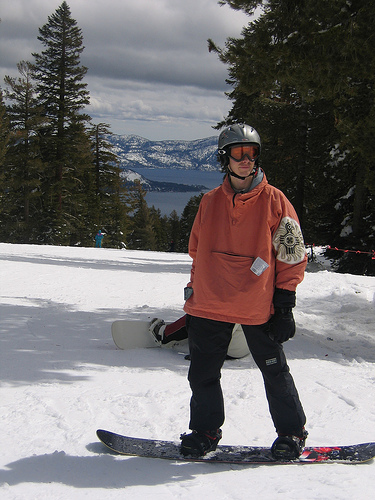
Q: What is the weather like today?
A: It is cloudy.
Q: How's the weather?
A: It is cloudy.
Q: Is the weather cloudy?
A: Yes, it is cloudy.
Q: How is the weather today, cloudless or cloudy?
A: It is cloudy.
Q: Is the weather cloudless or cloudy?
A: It is cloudy.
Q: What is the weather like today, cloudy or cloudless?
A: It is cloudy.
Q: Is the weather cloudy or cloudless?
A: It is cloudy.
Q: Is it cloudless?
A: No, it is cloudy.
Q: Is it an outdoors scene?
A: Yes, it is outdoors.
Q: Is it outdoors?
A: Yes, it is outdoors.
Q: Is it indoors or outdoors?
A: It is outdoors.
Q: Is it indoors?
A: No, it is outdoors.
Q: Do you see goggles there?
A: Yes, there are goggles.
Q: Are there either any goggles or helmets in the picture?
A: Yes, there are goggles.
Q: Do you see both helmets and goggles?
A: Yes, there are both goggles and a helmet.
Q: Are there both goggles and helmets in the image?
A: Yes, there are both goggles and a helmet.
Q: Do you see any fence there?
A: No, there are no fences.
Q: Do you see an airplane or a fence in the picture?
A: No, there are no fences or airplanes.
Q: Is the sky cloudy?
A: Yes, the sky is cloudy.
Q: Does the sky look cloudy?
A: Yes, the sky is cloudy.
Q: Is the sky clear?
A: No, the sky is cloudy.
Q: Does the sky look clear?
A: No, the sky is cloudy.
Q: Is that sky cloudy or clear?
A: The sky is cloudy.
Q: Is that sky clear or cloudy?
A: The sky is cloudy.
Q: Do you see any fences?
A: No, there are no fences.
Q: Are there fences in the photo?
A: No, there are no fences.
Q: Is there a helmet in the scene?
A: Yes, there is a helmet.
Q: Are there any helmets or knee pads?
A: Yes, there is a helmet.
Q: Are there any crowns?
A: No, there are no crowns.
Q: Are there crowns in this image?
A: No, there are no crowns.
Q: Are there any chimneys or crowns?
A: No, there are no crowns or chimneys.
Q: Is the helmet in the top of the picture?
A: Yes, the helmet is in the top of the image.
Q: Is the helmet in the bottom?
A: No, the helmet is in the top of the image.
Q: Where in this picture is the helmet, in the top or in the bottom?
A: The helmet is in the top of the image.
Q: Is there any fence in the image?
A: No, there are no fences.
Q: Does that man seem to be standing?
A: Yes, the man is standing.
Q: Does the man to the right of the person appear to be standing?
A: Yes, the man is standing.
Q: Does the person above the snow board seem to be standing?
A: Yes, the man is standing.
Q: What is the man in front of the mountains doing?
A: The man is standing.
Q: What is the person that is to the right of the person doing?
A: The man is standing.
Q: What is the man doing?
A: The man is standing.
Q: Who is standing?
A: The man is standing.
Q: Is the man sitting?
A: No, the man is standing.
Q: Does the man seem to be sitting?
A: No, the man is standing.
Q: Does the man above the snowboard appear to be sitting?
A: No, the man is standing.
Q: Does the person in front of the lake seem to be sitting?
A: No, the man is standing.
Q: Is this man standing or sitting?
A: The man is standing.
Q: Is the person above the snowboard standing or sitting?
A: The man is standing.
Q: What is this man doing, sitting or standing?
A: The man is standing.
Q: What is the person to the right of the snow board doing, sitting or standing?
A: The man is standing.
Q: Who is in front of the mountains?
A: The man is in front of the mountains.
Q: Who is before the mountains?
A: The man is in front of the mountains.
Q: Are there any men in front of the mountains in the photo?
A: Yes, there is a man in front of the mountains.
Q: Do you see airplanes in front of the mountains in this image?
A: No, there is a man in front of the mountains.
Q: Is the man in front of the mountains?
A: Yes, the man is in front of the mountains.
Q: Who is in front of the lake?
A: The man is in front of the lake.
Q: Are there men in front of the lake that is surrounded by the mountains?
A: Yes, there is a man in front of the lake.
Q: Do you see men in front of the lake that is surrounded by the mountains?
A: Yes, there is a man in front of the lake.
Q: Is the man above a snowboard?
A: Yes, the man is above a snowboard.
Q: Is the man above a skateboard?
A: No, the man is above a snowboard.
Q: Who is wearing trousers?
A: The man is wearing trousers.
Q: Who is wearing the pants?
A: The man is wearing trousers.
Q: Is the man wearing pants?
A: Yes, the man is wearing pants.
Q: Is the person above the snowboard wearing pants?
A: Yes, the man is wearing pants.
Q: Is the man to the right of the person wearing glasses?
A: No, the man is wearing pants.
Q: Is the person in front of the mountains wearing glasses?
A: No, the man is wearing pants.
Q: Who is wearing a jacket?
A: The man is wearing a jacket.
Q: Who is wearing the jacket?
A: The man is wearing a jacket.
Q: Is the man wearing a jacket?
A: Yes, the man is wearing a jacket.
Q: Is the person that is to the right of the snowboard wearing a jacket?
A: Yes, the man is wearing a jacket.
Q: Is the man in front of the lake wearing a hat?
A: No, the man is wearing a jacket.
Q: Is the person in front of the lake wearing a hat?
A: No, the man is wearing a jacket.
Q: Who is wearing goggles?
A: The man is wearing goggles.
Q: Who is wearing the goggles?
A: The man is wearing goggles.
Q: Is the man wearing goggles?
A: Yes, the man is wearing goggles.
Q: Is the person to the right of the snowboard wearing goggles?
A: Yes, the man is wearing goggles.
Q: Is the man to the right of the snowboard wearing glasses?
A: No, the man is wearing goggles.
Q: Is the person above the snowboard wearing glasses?
A: No, the man is wearing goggles.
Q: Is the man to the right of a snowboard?
A: Yes, the man is to the right of a snowboard.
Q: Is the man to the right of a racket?
A: No, the man is to the right of a snowboard.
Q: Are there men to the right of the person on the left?
A: Yes, there is a man to the right of the person.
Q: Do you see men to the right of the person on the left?
A: Yes, there is a man to the right of the person.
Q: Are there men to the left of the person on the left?
A: No, the man is to the right of the person.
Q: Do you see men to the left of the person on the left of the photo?
A: No, the man is to the right of the person.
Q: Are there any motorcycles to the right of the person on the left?
A: No, there is a man to the right of the person.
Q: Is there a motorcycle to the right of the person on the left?
A: No, there is a man to the right of the person.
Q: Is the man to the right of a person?
A: Yes, the man is to the right of a person.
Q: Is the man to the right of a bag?
A: No, the man is to the right of a person.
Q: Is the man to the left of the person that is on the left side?
A: No, the man is to the right of the person.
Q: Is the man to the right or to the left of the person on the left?
A: The man is to the right of the person.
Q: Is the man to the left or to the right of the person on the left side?
A: The man is to the right of the person.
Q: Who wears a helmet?
A: The man wears a helmet.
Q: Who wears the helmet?
A: The man wears a helmet.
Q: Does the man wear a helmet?
A: Yes, the man wears a helmet.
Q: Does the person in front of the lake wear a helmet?
A: Yes, the man wears a helmet.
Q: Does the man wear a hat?
A: No, the man wears a helmet.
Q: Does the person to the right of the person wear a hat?
A: No, the man wears a helmet.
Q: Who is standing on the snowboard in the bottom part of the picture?
A: The man is standing on the snowboard.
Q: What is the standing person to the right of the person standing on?
A: The man is standing on the snowboard.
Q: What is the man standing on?
A: The man is standing on the snowboard.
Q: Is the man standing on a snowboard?
A: Yes, the man is standing on a snowboard.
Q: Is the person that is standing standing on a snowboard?
A: Yes, the man is standing on a snowboard.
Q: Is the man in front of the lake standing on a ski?
A: No, the man is standing on a snowboard.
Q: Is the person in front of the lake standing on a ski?
A: No, the man is standing on a snowboard.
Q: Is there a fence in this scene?
A: No, there are no fences.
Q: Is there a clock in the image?
A: No, there are no clocks.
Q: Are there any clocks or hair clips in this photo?
A: No, there are no clocks or hair clips.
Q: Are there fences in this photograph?
A: No, there are no fences.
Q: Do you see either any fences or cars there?
A: No, there are no fences or cars.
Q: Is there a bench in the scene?
A: No, there are no benches.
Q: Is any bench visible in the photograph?
A: No, there are no benches.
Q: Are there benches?
A: No, there are no benches.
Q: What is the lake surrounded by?
A: The lake is surrounded by the mountains.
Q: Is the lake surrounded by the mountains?
A: Yes, the lake is surrounded by the mountains.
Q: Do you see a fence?
A: No, there are no fences.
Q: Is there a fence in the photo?
A: No, there are no fences.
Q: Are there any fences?
A: No, there are no fences.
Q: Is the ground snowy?
A: Yes, the ground is snowy.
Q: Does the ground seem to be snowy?
A: Yes, the ground is snowy.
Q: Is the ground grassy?
A: No, the ground is snowy.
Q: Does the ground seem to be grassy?
A: No, the ground is snowy.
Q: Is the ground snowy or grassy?
A: The ground is snowy.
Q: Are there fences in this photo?
A: No, there are no fences.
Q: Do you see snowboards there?
A: Yes, there is a snowboard.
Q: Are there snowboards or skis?
A: Yes, there is a snowboard.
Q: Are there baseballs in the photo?
A: No, there are no baseballs.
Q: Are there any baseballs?
A: No, there are no baseballs.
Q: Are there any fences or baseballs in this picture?
A: No, there are no baseballs or fences.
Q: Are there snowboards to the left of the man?
A: Yes, there is a snowboard to the left of the man.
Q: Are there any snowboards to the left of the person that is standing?
A: Yes, there is a snowboard to the left of the man.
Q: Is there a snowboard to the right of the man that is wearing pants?
A: No, the snowboard is to the left of the man.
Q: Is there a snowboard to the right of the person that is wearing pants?
A: No, the snowboard is to the left of the man.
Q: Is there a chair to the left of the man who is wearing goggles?
A: No, there is a snowboard to the left of the man.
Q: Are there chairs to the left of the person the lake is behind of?
A: No, there is a snowboard to the left of the man.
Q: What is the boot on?
A: The boot is on the snowboard.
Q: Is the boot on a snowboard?
A: Yes, the boot is on a snowboard.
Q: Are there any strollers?
A: No, there are no strollers.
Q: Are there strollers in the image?
A: No, there are no strollers.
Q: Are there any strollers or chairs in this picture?
A: No, there are no strollers or chairs.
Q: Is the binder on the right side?
A: Yes, the binder is on the right of the image.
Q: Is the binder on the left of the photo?
A: No, the binder is on the right of the image.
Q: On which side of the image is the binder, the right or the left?
A: The binder is on the right of the image.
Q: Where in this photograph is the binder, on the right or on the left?
A: The binder is on the right of the image.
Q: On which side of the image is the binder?
A: The binder is on the right of the image.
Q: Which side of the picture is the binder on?
A: The binder is on the right of the image.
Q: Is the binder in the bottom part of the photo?
A: Yes, the binder is in the bottom of the image.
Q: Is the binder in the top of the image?
A: No, the binder is in the bottom of the image.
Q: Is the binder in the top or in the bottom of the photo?
A: The binder is in the bottom of the image.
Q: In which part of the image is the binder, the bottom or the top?
A: The binder is in the bottom of the image.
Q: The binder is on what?
A: The binder is on the snowboard.